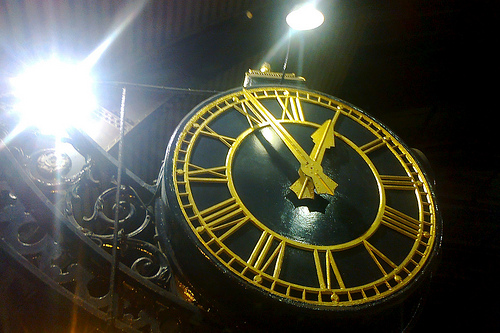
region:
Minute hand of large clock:
[232, 82, 337, 200]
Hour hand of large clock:
[299, 114, 336, 209]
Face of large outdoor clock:
[160, 83, 446, 309]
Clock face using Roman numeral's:
[165, 78, 442, 300]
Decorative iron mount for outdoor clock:
[25, 128, 152, 313]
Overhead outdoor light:
[274, 1, 331, 47]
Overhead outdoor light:
[18, 44, 93, 126]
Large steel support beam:
[116, 11, 222, 88]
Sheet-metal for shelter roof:
[120, 3, 174, 51]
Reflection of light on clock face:
[244, 116, 290, 159]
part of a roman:
[311, 248, 338, 287]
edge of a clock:
[230, 275, 274, 322]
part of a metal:
[128, 247, 161, 284]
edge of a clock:
[287, 299, 312, 320]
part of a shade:
[283, 170, 320, 222]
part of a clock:
[283, 255, 300, 282]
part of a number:
[207, 188, 244, 233]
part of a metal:
[96, 177, 111, 206]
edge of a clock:
[424, 242, 446, 269]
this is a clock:
[189, 115, 384, 264]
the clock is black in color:
[248, 157, 282, 196]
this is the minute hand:
[250, 104, 295, 153]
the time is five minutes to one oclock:
[232, 100, 354, 205]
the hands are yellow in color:
[277, 113, 348, 186]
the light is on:
[286, 2, 329, 32]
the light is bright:
[287, 7, 327, 31]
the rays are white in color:
[23, 55, 103, 130]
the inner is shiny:
[307, 201, 355, 227]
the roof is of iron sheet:
[152, 6, 198, 27]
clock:
[205, 81, 427, 301]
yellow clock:
[170, 87, 435, 299]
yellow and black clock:
[165, 85, 435, 295]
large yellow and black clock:
[190, 85, 410, 305]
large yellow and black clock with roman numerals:
[180, 91, 421, 308]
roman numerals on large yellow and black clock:
[168, 90, 430, 300]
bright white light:
[22, 59, 91, 132]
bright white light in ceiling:
[283, 2, 335, 45]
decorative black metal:
[28, 149, 145, 256]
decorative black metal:
[13, 213, 95, 303]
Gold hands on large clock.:
[268, 102, 332, 203]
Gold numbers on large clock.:
[219, 102, 388, 279]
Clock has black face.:
[218, 97, 388, 291]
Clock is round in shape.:
[168, 93, 396, 290]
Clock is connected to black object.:
[100, 126, 247, 258]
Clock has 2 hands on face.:
[199, 92, 351, 204]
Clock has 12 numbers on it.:
[174, 59, 381, 315]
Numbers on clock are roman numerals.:
[171, 47, 368, 305]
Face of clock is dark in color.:
[184, 69, 402, 283]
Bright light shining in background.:
[16, 56, 143, 184]